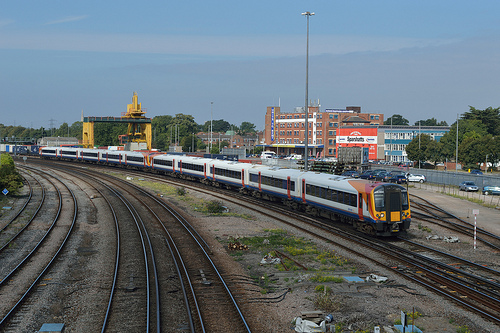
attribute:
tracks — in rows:
[7, 162, 219, 327]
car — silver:
[459, 175, 472, 195]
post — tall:
[297, 8, 318, 175]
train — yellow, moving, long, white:
[25, 147, 414, 258]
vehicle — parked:
[481, 185, 498, 197]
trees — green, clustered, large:
[403, 123, 498, 196]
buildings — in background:
[231, 105, 417, 170]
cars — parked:
[443, 176, 499, 212]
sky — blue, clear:
[18, 6, 222, 105]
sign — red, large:
[329, 121, 376, 165]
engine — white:
[293, 163, 421, 249]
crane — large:
[101, 80, 143, 149]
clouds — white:
[116, 31, 372, 60]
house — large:
[265, 103, 333, 160]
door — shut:
[387, 188, 398, 227]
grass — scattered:
[127, 180, 251, 214]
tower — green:
[87, 89, 189, 175]